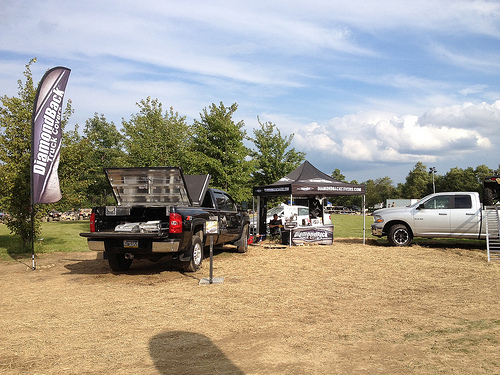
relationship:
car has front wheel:
[243, 202, 334, 244] [246, 230, 262, 244]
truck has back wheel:
[73, 165, 256, 284] [181, 234, 208, 277]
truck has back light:
[73, 165, 256, 284] [166, 212, 183, 239]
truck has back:
[73, 165, 256, 284] [74, 164, 193, 275]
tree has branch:
[0, 57, 77, 255] [61, 96, 77, 133]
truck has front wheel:
[73, 165, 256, 284] [236, 225, 251, 255]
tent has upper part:
[249, 154, 370, 254] [249, 158, 368, 203]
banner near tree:
[16, 65, 72, 270] [0, 57, 77, 255]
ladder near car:
[478, 200, 499, 264] [370, 192, 500, 247]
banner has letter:
[30, 65, 72, 270] [31, 158, 51, 170]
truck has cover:
[73, 165, 256, 284] [100, 165, 214, 208]